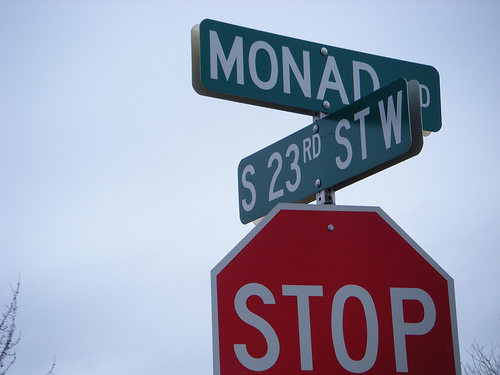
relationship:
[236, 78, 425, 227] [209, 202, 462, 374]
sign above stop sign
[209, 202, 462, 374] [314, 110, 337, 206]
stop sign on pole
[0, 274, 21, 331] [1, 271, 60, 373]
branch of tree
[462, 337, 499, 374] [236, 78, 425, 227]
grass near sign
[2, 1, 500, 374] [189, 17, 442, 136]
sky in background of sign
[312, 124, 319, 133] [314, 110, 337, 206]
bolt on pole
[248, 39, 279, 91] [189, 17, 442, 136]
letter on sign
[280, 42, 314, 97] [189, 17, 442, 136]
letter on sign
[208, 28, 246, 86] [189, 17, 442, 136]
letter on sign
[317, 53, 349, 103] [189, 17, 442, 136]
letter on sign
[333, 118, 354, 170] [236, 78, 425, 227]
letter on sign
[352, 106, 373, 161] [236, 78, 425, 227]
letter on sign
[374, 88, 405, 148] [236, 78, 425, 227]
letter on sign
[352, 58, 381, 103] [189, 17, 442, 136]
letter on sign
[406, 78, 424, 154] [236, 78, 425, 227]
edge of sign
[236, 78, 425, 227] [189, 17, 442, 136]
sign perpendicular to sign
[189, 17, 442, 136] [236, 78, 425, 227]
sign on top of sign